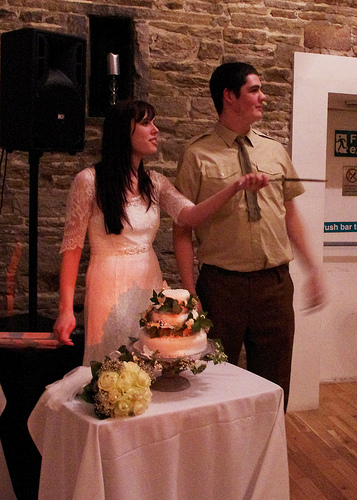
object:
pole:
[28, 150, 39, 315]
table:
[25, 359, 293, 500]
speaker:
[0, 26, 90, 156]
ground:
[285, 378, 357, 500]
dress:
[57, 165, 195, 366]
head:
[101, 98, 160, 156]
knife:
[268, 174, 329, 184]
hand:
[234, 171, 270, 195]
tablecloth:
[23, 346, 293, 497]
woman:
[50, 98, 271, 369]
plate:
[132, 337, 217, 363]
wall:
[137, 0, 298, 59]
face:
[131, 104, 160, 156]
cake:
[137, 285, 215, 359]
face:
[239, 73, 267, 123]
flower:
[96, 372, 116, 393]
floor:
[287, 383, 357, 500]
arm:
[57, 167, 95, 308]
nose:
[150, 122, 160, 135]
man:
[172, 60, 331, 414]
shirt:
[173, 120, 307, 273]